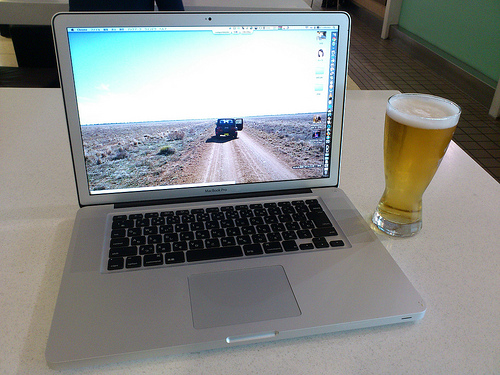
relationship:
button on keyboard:
[298, 242, 315, 249] [107, 195, 347, 264]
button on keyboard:
[281, 236, 300, 251] [46, 8, 428, 362]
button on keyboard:
[196, 210, 211, 222] [102, 196, 349, 276]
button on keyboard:
[149, 235, 161, 243] [102, 196, 349, 276]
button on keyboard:
[186, 245, 241, 260] [102, 196, 349, 276]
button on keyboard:
[106, 258, 123, 270] [102, 196, 349, 276]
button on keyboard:
[108, 237, 130, 247] [102, 196, 349, 276]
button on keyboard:
[283, 220, 303, 230] [102, 196, 349, 276]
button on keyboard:
[255, 218, 289, 245] [99, 190, 348, 266]